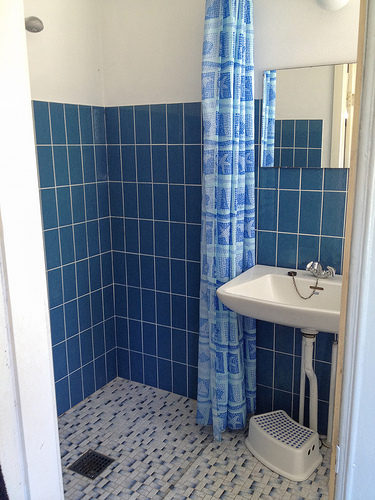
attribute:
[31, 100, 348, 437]
tiles — blue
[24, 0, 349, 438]
walls — blue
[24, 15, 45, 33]
shower head — gray, round, grey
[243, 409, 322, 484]
stool — white, blue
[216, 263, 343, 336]
sink — white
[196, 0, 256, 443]
shower curtain — blue, white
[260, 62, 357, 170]
mirror — small, hanging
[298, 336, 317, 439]
pipes — white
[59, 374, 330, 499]
floor — blue, white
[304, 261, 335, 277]
water fixtures — silver